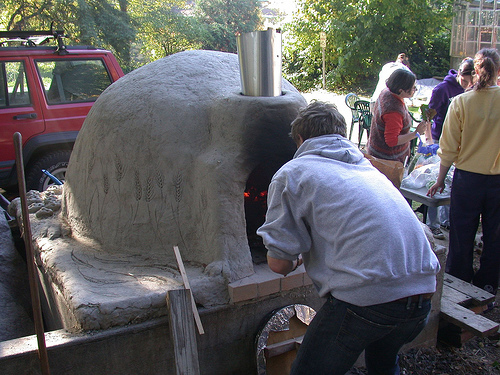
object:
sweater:
[438, 84, 500, 176]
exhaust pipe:
[232, 25, 284, 97]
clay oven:
[48, 118, 229, 269]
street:
[301, 84, 368, 101]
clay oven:
[7, 25, 351, 317]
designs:
[83, 144, 183, 250]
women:
[365, 62, 429, 197]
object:
[246, 299, 323, 374]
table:
[393, 170, 463, 257]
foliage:
[281, 4, 448, 88]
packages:
[399, 151, 460, 191]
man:
[255, 102, 442, 371]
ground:
[408, 340, 500, 369]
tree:
[299, 2, 456, 76]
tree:
[189, 2, 264, 50]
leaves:
[443, 7, 456, 17]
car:
[0, 28, 126, 199]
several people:
[253, 49, 500, 375]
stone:
[75, 47, 327, 257]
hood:
[292, 134, 365, 165]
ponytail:
[469, 53, 499, 93]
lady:
[426, 53, 476, 149]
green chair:
[354, 96, 372, 149]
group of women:
[367, 46, 500, 287]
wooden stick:
[7, 130, 52, 373]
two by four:
[163, 281, 204, 373]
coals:
[248, 179, 272, 213]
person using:
[252, 100, 445, 374]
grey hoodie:
[254, 134, 442, 308]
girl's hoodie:
[426, 68, 463, 145]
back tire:
[25, 150, 72, 192]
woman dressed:
[429, 48, 499, 289]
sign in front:
[319, 28, 329, 89]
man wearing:
[253, 132, 442, 375]